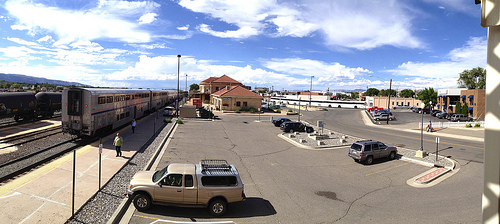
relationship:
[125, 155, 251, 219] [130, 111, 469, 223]
truck parked on street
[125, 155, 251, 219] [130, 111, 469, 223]
truck parked in lot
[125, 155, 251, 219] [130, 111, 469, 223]
truck in parking lot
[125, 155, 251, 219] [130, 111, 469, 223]
suv parked in lot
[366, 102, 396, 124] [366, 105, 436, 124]
vehicles parked in parking lot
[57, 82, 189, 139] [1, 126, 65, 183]
train on train tracks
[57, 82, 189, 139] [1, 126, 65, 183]
train on a track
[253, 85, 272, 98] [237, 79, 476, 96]
building in distance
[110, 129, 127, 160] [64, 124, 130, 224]
people walking on sidewalk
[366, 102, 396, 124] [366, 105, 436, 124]
cars parked on lot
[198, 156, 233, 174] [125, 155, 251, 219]
racks on top of truck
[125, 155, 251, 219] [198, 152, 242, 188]
truck has add on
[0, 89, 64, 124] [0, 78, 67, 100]
train station in background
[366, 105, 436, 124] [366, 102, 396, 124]
parking with cars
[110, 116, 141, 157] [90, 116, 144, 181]
people standing on platform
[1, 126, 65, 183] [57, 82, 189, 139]
tracks by train